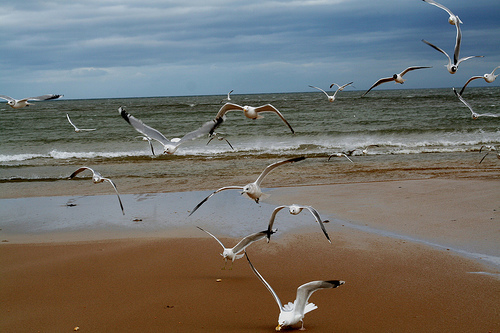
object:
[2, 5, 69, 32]
clouds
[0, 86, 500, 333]
coast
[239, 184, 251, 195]
head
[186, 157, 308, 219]
bird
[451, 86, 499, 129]
bird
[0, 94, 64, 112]
bird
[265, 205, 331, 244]
bird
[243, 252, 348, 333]
bird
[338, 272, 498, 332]
sand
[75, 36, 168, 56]
clouds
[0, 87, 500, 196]
waters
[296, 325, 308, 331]
foot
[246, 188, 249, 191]
eye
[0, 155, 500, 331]
ground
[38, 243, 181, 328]
sand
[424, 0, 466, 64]
bird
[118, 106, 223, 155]
bird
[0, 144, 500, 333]
beach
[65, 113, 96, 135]
birds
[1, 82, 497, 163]
ocean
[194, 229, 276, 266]
bird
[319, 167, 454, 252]
sand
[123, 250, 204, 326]
sand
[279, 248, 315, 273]
sand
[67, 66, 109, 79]
cloud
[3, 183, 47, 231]
wet sand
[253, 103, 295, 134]
wing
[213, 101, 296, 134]
bird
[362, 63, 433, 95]
bird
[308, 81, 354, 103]
bird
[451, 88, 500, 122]
bird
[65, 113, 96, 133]
bird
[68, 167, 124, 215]
bird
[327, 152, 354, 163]
bird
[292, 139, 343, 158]
waves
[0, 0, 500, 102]
sky